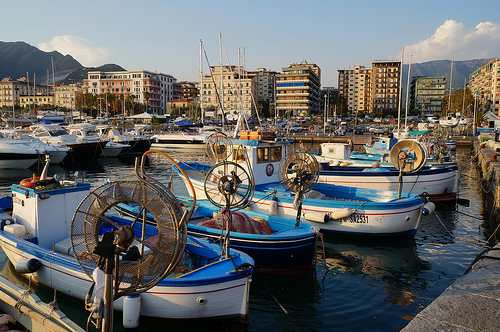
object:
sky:
[0, 0, 497, 91]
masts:
[198, 38, 206, 124]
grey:
[396, 242, 498, 331]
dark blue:
[195, 266, 232, 275]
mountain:
[0, 39, 130, 90]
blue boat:
[100, 182, 320, 270]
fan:
[65, 154, 190, 293]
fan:
[202, 159, 257, 215]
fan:
[386, 137, 428, 175]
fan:
[272, 146, 323, 200]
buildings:
[78, 68, 179, 116]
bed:
[103, 182, 320, 241]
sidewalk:
[398, 239, 499, 331]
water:
[0, 150, 490, 331]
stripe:
[184, 182, 425, 217]